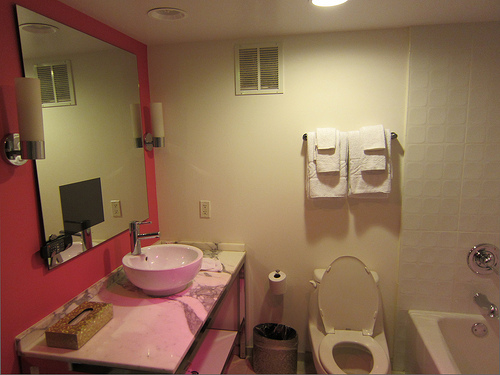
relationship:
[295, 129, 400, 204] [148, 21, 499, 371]
towels on wall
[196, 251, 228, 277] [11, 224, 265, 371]
tissue on counter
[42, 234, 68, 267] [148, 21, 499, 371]
holder on wall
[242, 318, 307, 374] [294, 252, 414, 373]
can under toilet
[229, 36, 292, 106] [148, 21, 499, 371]
vent on wall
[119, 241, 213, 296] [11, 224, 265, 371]
sink on counter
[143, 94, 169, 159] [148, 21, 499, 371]
light on wall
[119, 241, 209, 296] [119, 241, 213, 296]
sink white sink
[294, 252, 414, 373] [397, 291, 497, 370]
toilet next to tub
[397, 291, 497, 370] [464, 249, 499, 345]
tub with plumbing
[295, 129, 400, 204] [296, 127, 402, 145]
towels on bar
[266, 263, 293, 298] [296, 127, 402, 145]
paper on bar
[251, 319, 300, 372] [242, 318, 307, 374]
can brown can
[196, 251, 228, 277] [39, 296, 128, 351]
tissue brown box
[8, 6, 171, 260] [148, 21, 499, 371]
mirror on wall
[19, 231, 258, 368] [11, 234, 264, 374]
vanity with countertop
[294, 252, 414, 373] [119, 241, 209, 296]
toilet a sink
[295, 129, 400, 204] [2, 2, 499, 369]
towels in bathroom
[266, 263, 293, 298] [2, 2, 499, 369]
paper in bathroom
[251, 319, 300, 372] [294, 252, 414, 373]
can next to toilet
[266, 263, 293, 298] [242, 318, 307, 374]
paper above can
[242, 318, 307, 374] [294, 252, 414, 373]
can next to toilet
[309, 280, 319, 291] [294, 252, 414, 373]
handle to toilet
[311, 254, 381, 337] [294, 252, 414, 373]
seat of toilet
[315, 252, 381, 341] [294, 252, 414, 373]
lid of toilet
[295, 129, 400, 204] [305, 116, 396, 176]
towels hanging up